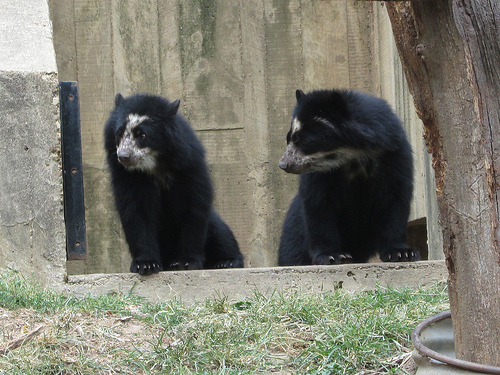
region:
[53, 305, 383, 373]
the grass is short and green.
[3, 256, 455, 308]
a grey cement ground.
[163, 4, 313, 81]
a green and grey cement wall.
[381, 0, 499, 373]
a wooden tree stem.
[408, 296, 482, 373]
a piece of green metal around a tree.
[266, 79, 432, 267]
a black hairy bear.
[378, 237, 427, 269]
a bears paws with sharp nails.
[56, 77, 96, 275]
a black piece of metal.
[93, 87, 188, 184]
a bear with a white and black face.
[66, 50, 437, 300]
two bears sit together in the wilderness.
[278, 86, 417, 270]
a small black furry bear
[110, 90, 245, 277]
a small black furry bear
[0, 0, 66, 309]
concrete pillar attached to a concrete wall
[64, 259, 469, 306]
a short concrete wall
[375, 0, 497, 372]
a tree trunk with no branch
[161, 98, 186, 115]
a bears ear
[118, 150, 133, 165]
a bears nose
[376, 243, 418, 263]
a clawed bears paw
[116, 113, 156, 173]
a lighter patch of fur on a bears face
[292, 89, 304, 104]
a bears ear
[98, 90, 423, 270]
a pair of black and white animals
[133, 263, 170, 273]
some very sharp claws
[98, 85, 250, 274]
a bear like animal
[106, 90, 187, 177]
a black and white face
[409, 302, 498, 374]
a thick metal ring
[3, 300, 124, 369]
a dried patch of grass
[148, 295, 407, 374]
a patchy lawn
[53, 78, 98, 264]
a rusty metal hinge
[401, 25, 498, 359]
a scarred tree trunk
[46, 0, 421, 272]
a large wooden door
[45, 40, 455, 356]
Picture taken outdoors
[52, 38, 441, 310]
Picture taken during the day.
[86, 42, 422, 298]
Two fluffy animals.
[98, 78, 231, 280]
The animal has black hair.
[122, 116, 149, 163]
The face has white hair.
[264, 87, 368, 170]
The animal is looking at the other animal.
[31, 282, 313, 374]
The grass is cut short.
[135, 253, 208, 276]
The animal have sharp claws.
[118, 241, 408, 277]
The animals stand on a ledge.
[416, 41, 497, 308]
A large tree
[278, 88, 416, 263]
black and white animal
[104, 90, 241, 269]
black and white animal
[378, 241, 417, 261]
black furry animal paw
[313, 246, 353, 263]
black furry animal paw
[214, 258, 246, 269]
black furry animal paw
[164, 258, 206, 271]
black furry animal paw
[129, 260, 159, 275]
black furry animal paw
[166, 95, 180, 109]
small black animal ear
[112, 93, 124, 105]
small black animal ear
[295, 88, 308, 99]
small black animal ear